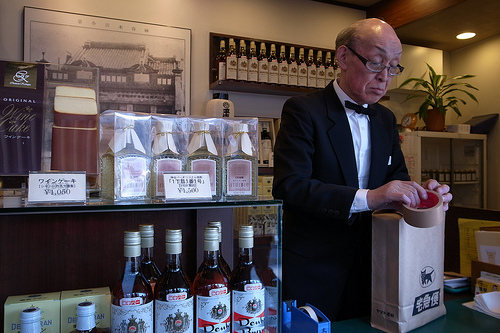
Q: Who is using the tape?
A: The man.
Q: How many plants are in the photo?
A: 1.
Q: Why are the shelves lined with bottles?
A: Merchandise.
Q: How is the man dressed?
A: In a tuxedo.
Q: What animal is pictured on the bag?
A: Cat.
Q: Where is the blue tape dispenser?
A: On the left side of the bag.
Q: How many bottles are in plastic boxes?
A: 4.